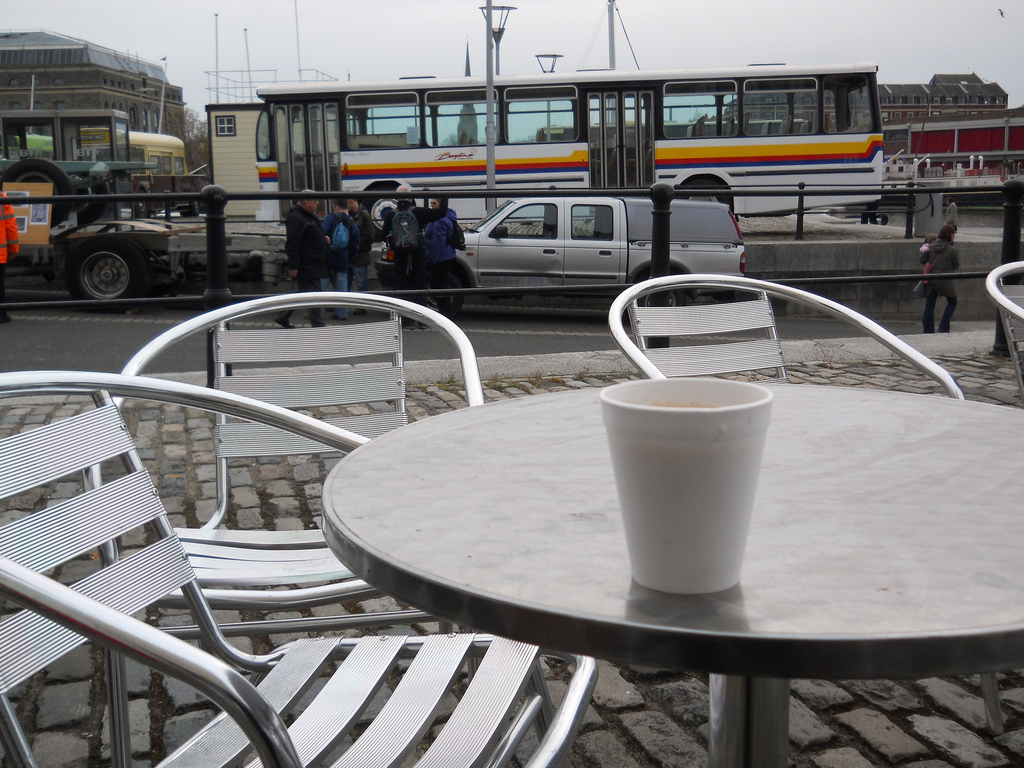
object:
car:
[0, 152, 184, 313]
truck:
[377, 198, 747, 316]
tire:
[79, 255, 131, 301]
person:
[907, 211, 957, 333]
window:
[345, 105, 421, 151]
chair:
[0, 372, 602, 768]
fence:
[2, 178, 1020, 405]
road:
[0, 266, 1011, 365]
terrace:
[2, 324, 1020, 765]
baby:
[918, 233, 938, 274]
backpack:
[328, 213, 355, 252]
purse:
[444, 214, 466, 251]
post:
[710, 669, 793, 765]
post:
[202, 178, 229, 304]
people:
[273, 173, 467, 340]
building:
[5, 24, 192, 176]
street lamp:
[471, 4, 515, 76]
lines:
[250, 134, 879, 182]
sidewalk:
[555, 657, 1015, 765]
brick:
[833, 703, 932, 760]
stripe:
[399, 161, 884, 179]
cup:
[599, 377, 772, 593]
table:
[312, 366, 1024, 768]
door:
[280, 102, 337, 217]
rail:
[370, 78, 537, 191]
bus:
[249, 63, 911, 223]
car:
[373, 196, 746, 315]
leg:
[699, 675, 794, 768]